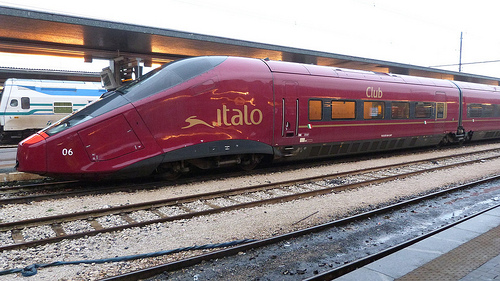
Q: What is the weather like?
A: It is cloudy.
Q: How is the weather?
A: It is cloudy.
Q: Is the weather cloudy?
A: Yes, it is cloudy.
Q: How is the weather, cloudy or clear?
A: It is cloudy.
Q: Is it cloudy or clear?
A: It is cloudy.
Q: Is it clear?
A: No, it is cloudy.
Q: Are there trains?
A: Yes, there is a train.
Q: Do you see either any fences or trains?
A: Yes, there is a train.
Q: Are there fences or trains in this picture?
A: Yes, there is a train.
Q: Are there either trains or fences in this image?
A: Yes, there is a train.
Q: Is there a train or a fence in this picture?
A: Yes, there is a train.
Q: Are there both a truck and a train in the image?
A: No, there is a train but no trucks.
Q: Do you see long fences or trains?
A: Yes, there is a long train.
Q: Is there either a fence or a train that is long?
A: Yes, the train is long.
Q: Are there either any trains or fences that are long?
A: Yes, the train is long.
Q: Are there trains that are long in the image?
A: Yes, there is a long train.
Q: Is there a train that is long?
A: Yes, there is a train that is long.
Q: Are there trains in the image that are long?
A: Yes, there is a train that is long.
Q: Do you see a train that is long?
A: Yes, there is a train that is long.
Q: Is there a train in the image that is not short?
A: Yes, there is a long train.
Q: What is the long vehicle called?
A: The vehicle is a train.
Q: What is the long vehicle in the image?
A: The vehicle is a train.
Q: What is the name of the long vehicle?
A: The vehicle is a train.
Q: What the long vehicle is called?
A: The vehicle is a train.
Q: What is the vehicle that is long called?
A: The vehicle is a train.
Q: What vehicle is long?
A: The vehicle is a train.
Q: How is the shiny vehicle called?
A: The vehicle is a train.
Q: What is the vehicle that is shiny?
A: The vehicle is a train.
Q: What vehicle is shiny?
A: The vehicle is a train.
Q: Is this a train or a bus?
A: This is a train.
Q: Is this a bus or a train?
A: This is a train.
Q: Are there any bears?
A: No, there are no bears.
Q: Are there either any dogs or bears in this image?
A: No, there are no bears or dogs.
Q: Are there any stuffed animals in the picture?
A: No, there are no stuffed animals.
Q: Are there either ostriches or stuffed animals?
A: No, there are no stuffed animals or ostriches.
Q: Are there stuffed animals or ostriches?
A: No, there are no stuffed animals or ostriches.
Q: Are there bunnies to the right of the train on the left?
A: Yes, there is a bunny to the right of the train.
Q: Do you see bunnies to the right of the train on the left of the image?
A: Yes, there is a bunny to the right of the train.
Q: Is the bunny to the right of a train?
A: Yes, the bunny is to the right of a train.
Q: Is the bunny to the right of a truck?
A: No, the bunny is to the right of a train.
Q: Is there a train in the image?
A: Yes, there is a train.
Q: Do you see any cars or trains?
A: Yes, there is a train.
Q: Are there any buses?
A: No, there are no buses.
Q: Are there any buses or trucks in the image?
A: No, there are no buses or trucks.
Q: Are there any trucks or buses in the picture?
A: No, there are no buses or trucks.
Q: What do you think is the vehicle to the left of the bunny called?
A: The vehicle is a train.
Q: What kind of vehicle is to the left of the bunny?
A: The vehicle is a train.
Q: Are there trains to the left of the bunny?
A: Yes, there is a train to the left of the bunny.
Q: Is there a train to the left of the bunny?
A: Yes, there is a train to the left of the bunny.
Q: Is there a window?
A: Yes, there is a window.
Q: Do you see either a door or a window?
A: Yes, there is a window.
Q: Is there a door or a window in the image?
A: Yes, there is a window.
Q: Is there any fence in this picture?
A: No, there are no fences.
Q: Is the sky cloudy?
A: Yes, the sky is cloudy.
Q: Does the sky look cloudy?
A: Yes, the sky is cloudy.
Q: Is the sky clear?
A: No, the sky is cloudy.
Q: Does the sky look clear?
A: No, the sky is cloudy.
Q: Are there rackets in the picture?
A: No, there are no rackets.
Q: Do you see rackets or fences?
A: No, there are no rackets or fences.